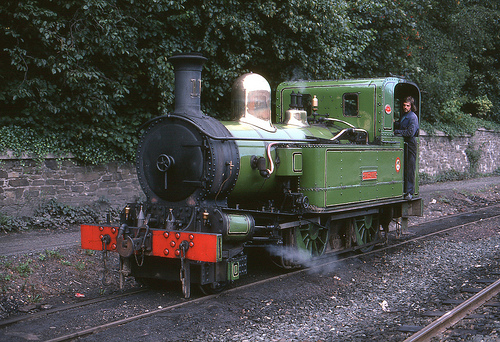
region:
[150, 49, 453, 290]
small and green train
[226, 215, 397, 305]
steam emanating from train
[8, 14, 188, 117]
green trees behind train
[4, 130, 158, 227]
brown stone on wall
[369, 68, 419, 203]
man is in train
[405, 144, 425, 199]
man has black pants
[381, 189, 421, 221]
man has black shoes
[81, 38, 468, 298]
train on the tracks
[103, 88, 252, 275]
front of the train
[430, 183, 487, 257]
track behind the train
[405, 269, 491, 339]
track next to the train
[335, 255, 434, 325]
rocks on the ground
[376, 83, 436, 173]
person in the train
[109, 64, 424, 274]
green, black and red train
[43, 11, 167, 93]
leaves next to train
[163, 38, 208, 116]
The smoke stack of the trian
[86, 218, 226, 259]
The red bumper of the train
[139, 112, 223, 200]
The front circle of the train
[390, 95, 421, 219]
The man standing in the train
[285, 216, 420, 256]
The wheels of the train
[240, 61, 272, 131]
The gold shiny part of the train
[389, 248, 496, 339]
The tracks of the train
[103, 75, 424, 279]
A green train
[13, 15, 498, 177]
The trees that are behind the train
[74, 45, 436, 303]
a train engine on train tracks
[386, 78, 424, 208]
a man on a train engine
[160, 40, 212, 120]
the smoke stack of a train engine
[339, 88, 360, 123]
a window in a train engine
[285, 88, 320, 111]
a window in a train engine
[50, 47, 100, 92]
the leaves of a tree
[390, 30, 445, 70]
the leaves of a tree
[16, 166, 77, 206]
the bricks of a brick wall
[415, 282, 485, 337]
a track of a set of train tracks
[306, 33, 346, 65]
the leaves of a tree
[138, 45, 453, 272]
green train on track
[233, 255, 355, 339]
grey ballast near train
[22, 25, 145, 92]
green trees behind fence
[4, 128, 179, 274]
grey rock wall behind train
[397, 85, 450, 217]
man stands on train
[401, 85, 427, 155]
man has blue shirt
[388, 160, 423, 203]
man has black shoes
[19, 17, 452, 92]
thick green grove of trees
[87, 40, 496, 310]
a train in the background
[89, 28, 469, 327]
a green train in the background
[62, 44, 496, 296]
a train on tracks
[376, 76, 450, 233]
a person in the train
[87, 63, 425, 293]
little green train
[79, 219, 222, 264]
red front of train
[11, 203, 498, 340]
metal rusty train tracks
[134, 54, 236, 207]
black front of green train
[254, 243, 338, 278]
white smoke going out green train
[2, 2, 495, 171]
dark green bushes in the background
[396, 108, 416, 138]
blue t-shirt of man standing in train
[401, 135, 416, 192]
dark jeans of man standing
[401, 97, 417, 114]
dark large man's hair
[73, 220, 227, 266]
the front bumper is red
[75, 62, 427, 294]
the locomotive has a 2-4-0-T wheel arrangement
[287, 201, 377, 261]
these wheels are the drivers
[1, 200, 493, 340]
the track is narrow gauge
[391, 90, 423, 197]
this is the engineer